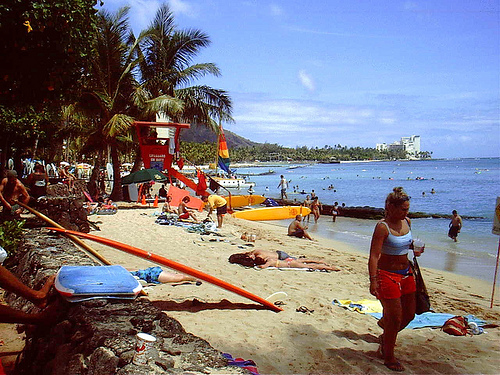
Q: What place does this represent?
A: It represents the beach.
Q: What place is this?
A: It is a beach.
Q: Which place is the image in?
A: It is at the beach.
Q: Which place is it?
A: It is a beach.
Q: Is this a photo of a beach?
A: Yes, it is showing a beach.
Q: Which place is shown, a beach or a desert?
A: It is a beach.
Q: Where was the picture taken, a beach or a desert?
A: It was taken at a beach.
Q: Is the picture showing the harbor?
A: No, the picture is showing the beach.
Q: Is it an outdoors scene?
A: Yes, it is outdoors.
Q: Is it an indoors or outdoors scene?
A: It is outdoors.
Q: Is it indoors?
A: No, it is outdoors.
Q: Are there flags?
A: Yes, there is a flag.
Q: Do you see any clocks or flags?
A: Yes, there is a flag.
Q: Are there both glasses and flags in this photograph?
A: No, there is a flag but no glasses.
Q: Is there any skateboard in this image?
A: No, there are no skateboards.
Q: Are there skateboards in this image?
A: No, there are no skateboards.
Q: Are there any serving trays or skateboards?
A: No, there are no skateboards or serving trays.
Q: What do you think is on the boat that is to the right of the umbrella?
A: The flag is on the boat.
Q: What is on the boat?
A: The flag is on the boat.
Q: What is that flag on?
A: The flag is on the boat.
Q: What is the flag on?
A: The flag is on the boat.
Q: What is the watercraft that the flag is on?
A: The watercraft is a boat.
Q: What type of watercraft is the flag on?
A: The flag is on the boat.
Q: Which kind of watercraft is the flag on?
A: The flag is on the boat.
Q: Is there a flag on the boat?
A: Yes, there is a flag on the boat.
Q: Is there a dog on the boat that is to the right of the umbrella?
A: No, there is a flag on the boat.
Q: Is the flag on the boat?
A: Yes, the flag is on the boat.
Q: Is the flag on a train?
A: No, the flag is on the boat.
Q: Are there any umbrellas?
A: Yes, there is an umbrella.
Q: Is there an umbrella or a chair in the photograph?
A: Yes, there is an umbrella.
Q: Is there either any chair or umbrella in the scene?
A: Yes, there is an umbrella.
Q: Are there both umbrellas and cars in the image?
A: No, there is an umbrella but no cars.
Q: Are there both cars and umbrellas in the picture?
A: No, there is an umbrella but no cars.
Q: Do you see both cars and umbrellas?
A: No, there is an umbrella but no cars.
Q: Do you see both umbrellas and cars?
A: No, there is an umbrella but no cars.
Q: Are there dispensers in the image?
A: No, there are no dispensers.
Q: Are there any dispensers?
A: No, there are no dispensers.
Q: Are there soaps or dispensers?
A: No, there are no dispensers or soaps.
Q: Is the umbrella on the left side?
A: Yes, the umbrella is on the left of the image.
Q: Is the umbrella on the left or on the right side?
A: The umbrella is on the left of the image.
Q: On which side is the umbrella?
A: The umbrella is on the left of the image.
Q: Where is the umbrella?
A: The umbrella is on the beach.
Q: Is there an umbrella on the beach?
A: Yes, there is an umbrella on the beach.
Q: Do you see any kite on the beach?
A: No, there is an umbrella on the beach.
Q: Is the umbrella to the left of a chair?
A: No, the umbrella is to the left of the surf board.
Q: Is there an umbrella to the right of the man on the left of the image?
A: Yes, there is an umbrella to the right of the man.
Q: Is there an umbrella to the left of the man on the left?
A: No, the umbrella is to the right of the man.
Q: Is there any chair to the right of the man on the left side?
A: No, there is an umbrella to the right of the man.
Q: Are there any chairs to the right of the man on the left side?
A: No, there is an umbrella to the right of the man.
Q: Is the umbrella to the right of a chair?
A: No, the umbrella is to the right of the man.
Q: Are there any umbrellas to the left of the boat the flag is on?
A: Yes, there is an umbrella to the left of the boat.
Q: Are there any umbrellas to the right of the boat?
A: No, the umbrella is to the left of the boat.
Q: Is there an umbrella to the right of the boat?
A: No, the umbrella is to the left of the boat.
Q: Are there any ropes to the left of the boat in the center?
A: No, there is an umbrella to the left of the boat.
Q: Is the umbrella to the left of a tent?
A: No, the umbrella is to the left of a boat.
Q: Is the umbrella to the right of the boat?
A: No, the umbrella is to the left of the boat.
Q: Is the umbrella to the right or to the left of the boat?
A: The umbrella is to the left of the boat.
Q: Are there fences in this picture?
A: No, there are no fences.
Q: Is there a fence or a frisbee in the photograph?
A: No, there are no fences or frisbees.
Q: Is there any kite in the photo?
A: No, there are no kites.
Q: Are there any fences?
A: No, there are no fences.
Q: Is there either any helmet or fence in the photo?
A: No, there are no fences or helmets.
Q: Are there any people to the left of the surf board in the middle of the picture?
A: Yes, there is a person to the left of the surfboard.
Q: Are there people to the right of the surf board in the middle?
A: No, the person is to the left of the surfboard.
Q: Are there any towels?
A: Yes, there is a towel.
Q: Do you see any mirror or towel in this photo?
A: Yes, there is a towel.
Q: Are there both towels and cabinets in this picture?
A: No, there is a towel but no cabinets.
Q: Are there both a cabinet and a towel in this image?
A: No, there is a towel but no cabinets.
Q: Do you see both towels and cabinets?
A: No, there is a towel but no cabinets.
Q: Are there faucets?
A: No, there are no faucets.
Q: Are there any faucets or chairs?
A: No, there are no faucets or chairs.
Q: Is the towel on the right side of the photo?
A: Yes, the towel is on the right of the image.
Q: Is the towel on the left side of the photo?
A: No, the towel is on the right of the image.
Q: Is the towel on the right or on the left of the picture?
A: The towel is on the right of the image.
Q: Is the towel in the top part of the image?
A: No, the towel is in the bottom of the image.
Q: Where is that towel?
A: The towel is on the sand.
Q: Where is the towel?
A: The towel is on the sand.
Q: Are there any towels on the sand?
A: Yes, there is a towel on the sand.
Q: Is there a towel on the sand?
A: Yes, there is a towel on the sand.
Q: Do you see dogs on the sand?
A: No, there is a towel on the sand.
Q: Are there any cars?
A: No, there are no cars.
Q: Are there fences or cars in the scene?
A: No, there are no cars or fences.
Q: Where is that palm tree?
A: The palm tree is on the beach.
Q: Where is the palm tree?
A: The palm tree is on the beach.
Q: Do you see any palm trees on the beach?
A: Yes, there is a palm tree on the beach.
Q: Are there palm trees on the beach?
A: Yes, there is a palm tree on the beach.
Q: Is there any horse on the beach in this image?
A: No, there is a palm tree on the beach.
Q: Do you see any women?
A: Yes, there is a woman.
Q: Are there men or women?
A: Yes, there is a woman.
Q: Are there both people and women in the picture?
A: Yes, there are both a woman and a person.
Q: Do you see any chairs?
A: No, there are no chairs.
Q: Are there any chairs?
A: No, there are no chairs.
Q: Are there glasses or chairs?
A: No, there are no chairs or glasses.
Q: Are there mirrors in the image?
A: No, there are no mirrors.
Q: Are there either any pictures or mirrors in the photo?
A: No, there are no mirrors or pictures.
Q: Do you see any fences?
A: No, there are no fences.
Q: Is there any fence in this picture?
A: No, there are no fences.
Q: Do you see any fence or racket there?
A: No, there are no fences or rackets.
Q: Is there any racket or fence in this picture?
A: No, there are no fences or rackets.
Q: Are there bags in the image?
A: Yes, there is a bag.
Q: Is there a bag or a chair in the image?
A: Yes, there is a bag.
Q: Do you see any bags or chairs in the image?
A: Yes, there is a bag.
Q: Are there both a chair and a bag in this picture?
A: No, there is a bag but no chairs.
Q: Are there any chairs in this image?
A: No, there are no chairs.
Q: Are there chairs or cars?
A: No, there are no chairs or cars.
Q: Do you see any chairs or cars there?
A: No, there are no chairs or cars.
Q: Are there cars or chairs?
A: No, there are no chairs or cars.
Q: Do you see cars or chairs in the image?
A: No, there are no chairs or cars.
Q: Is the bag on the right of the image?
A: Yes, the bag is on the right of the image.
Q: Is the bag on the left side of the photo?
A: No, the bag is on the right of the image.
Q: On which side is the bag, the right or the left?
A: The bag is on the right of the image.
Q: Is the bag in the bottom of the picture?
A: Yes, the bag is in the bottom of the image.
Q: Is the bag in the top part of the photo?
A: No, the bag is in the bottom of the image.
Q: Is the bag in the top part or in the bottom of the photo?
A: The bag is in the bottom of the image.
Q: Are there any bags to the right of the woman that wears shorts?
A: Yes, there is a bag to the right of the woman.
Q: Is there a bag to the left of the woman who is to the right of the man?
A: No, the bag is to the right of the woman.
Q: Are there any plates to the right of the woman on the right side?
A: No, there is a bag to the right of the woman.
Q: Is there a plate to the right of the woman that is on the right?
A: No, there is a bag to the right of the woman.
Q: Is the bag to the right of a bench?
A: No, the bag is to the right of the woman.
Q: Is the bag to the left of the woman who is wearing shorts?
A: No, the bag is to the right of the woman.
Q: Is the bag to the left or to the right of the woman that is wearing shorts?
A: The bag is to the right of the woman.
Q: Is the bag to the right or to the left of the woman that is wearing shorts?
A: The bag is to the right of the woman.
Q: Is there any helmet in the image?
A: No, there are no helmets.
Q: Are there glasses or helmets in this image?
A: No, there are no helmets or glasses.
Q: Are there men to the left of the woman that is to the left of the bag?
A: Yes, there is a man to the left of the woman.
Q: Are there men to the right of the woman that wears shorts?
A: No, the man is to the left of the woman.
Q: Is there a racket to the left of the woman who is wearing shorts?
A: No, there is a man to the left of the woman.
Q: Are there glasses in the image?
A: No, there are no glasses.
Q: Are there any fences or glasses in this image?
A: No, there are no glasses or fences.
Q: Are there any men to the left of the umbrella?
A: Yes, there is a man to the left of the umbrella.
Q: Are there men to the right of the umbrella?
A: No, the man is to the left of the umbrella.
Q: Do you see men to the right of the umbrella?
A: No, the man is to the left of the umbrella.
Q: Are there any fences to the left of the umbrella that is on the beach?
A: No, there is a man to the left of the umbrella.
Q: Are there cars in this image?
A: No, there are no cars.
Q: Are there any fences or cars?
A: No, there are no cars or fences.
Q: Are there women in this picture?
A: Yes, there is a woman.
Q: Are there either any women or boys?
A: Yes, there is a woman.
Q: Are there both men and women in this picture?
A: Yes, there are both a woman and a man.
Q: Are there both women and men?
A: Yes, there are both a woman and a man.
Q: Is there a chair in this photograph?
A: No, there are no chairs.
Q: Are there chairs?
A: No, there are no chairs.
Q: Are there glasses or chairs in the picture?
A: No, there are no chairs or glasses.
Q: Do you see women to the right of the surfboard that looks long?
A: Yes, there is a woman to the right of the surfboard.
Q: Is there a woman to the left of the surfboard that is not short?
A: No, the woman is to the right of the surfboard.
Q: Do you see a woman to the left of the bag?
A: Yes, there is a woman to the left of the bag.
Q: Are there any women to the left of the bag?
A: Yes, there is a woman to the left of the bag.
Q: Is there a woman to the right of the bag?
A: No, the woman is to the left of the bag.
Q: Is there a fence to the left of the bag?
A: No, there is a woman to the left of the bag.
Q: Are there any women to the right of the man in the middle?
A: Yes, there is a woman to the right of the man.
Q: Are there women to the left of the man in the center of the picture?
A: No, the woman is to the right of the man.